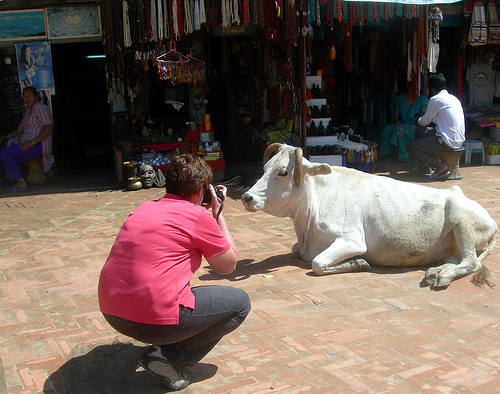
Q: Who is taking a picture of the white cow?
A: The man in the red shirt.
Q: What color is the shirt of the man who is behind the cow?
A: White.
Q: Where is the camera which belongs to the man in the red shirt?
A: In his hands.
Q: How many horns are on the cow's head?
A: Two.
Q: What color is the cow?
A: White.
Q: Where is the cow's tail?
A: On the ground.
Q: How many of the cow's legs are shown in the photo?
A: Two.